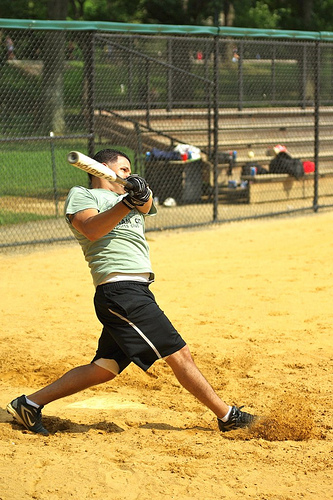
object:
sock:
[217, 405, 232, 423]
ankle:
[214, 404, 230, 419]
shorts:
[90, 280, 185, 372]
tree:
[29, 0, 84, 137]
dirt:
[211, 238, 241, 247]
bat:
[67, 150, 135, 190]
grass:
[2, 146, 40, 180]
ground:
[0, 194, 333, 500]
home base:
[72, 392, 135, 425]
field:
[0, 205, 333, 286]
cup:
[181, 153, 188, 161]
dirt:
[207, 459, 287, 490]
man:
[6, 148, 261, 437]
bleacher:
[93, 105, 332, 205]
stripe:
[106, 307, 162, 359]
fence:
[0, 18, 333, 248]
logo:
[26, 412, 36, 427]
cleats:
[6, 394, 49, 437]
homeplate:
[68, 393, 145, 411]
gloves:
[123, 173, 152, 203]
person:
[0, 34, 16, 59]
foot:
[217, 405, 259, 432]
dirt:
[263, 401, 315, 441]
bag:
[269, 151, 304, 181]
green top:
[134, 0, 256, 64]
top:
[122, 21, 243, 40]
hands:
[123, 173, 152, 203]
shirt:
[64, 185, 158, 288]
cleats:
[217, 405, 259, 433]